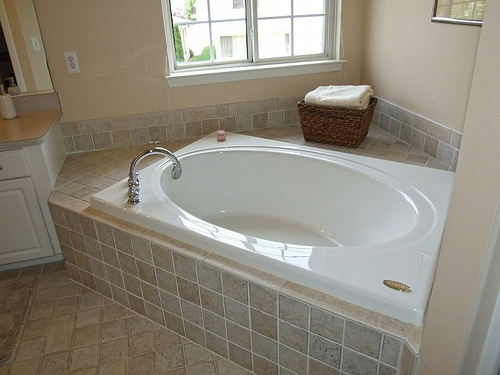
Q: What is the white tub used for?
A: Bathing.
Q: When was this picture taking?
A: Daytime.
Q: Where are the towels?
A: Basket.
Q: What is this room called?
A: Bathroom.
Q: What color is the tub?
A: White.